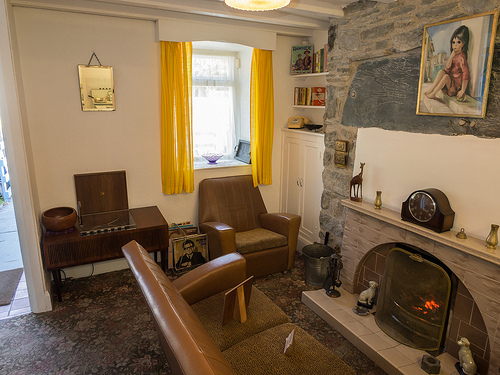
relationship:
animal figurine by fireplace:
[359, 281, 379, 306] [300, 197, 497, 373]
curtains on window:
[159, 40, 196, 195] [174, 44, 251, 174]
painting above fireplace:
[417, 14, 496, 116] [303, 180, 498, 366]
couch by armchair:
[122, 239, 362, 373] [195, 162, 311, 267]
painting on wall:
[426, 21, 489, 115] [343, 32, 398, 99]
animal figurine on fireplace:
[359, 277, 378, 306] [300, 197, 497, 373]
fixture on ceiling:
[220, 0, 293, 14] [111, 0, 360, 27]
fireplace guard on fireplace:
[372, 247, 453, 345] [318, 189, 498, 369]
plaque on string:
[78, 69, 113, 109] [83, 48, 102, 67]